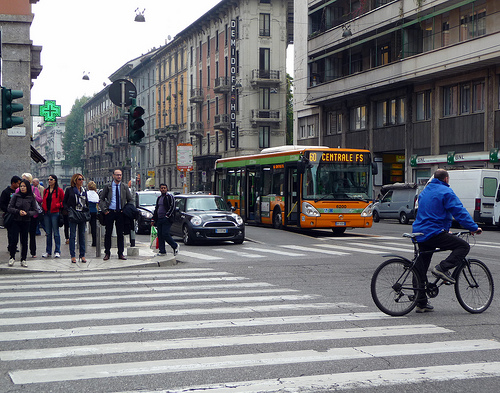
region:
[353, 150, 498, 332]
a man on a bicycle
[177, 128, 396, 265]
an orange and green bus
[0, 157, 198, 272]
people waiting to cross the street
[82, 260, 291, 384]
crosswalk painted with white lines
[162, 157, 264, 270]
car stopped on the street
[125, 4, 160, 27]
lights in the sky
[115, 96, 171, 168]
street light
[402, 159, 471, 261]
a blue jacket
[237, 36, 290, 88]
small balcony off of a building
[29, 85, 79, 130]
a green plus sign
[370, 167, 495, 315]
A man on a bike.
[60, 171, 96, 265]
A lady waiting to cross the street.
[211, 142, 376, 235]
An orange and green bus.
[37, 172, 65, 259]
A lady in a red shirt.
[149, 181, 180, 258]
A man walking across the street.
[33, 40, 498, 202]
Buildings on the right side of street.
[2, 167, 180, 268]
Lots of people on the sidewalk.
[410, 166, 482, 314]
A man in a blue jacket.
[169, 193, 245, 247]
A black car in the road.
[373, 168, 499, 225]
Parked cars on the street.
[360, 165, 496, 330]
A man is on a bike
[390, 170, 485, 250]
Man is wearing a blue coat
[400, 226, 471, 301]
Man is wearng black pants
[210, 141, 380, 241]
The bus is orange in color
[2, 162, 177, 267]
A group of people as the crosswalk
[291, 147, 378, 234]
front view of a bus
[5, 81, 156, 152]
Traffic lights are dark green in color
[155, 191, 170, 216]
Person is wearing a purple shirt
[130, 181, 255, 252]
Two cars in the foreground are stopped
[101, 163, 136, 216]
Man is wearing a dress shirt and blue tie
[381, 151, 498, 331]
a man riding a bicycle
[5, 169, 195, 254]
people crossing the street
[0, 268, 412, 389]
the crosswalk of the street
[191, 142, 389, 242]
the bus in the street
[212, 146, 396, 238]
the bus is numebr 60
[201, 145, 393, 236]
the bus is orange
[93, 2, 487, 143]
the buildings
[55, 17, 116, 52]
the sky is gray and cloudy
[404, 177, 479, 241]
the man wearing the blue jacket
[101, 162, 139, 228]
the man wearing the tie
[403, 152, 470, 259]
the man is biking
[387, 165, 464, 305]
the man is biking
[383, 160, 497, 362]
the man is biking